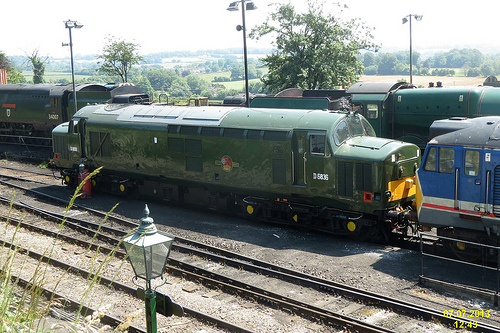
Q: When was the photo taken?
A: Daytime.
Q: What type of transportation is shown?
A: Trains.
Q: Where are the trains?
A: Tracks.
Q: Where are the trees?
A: Background.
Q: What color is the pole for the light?
A: Green.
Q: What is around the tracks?
A: Gravels.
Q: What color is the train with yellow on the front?
A: Green.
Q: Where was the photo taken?
A: In a train yard.